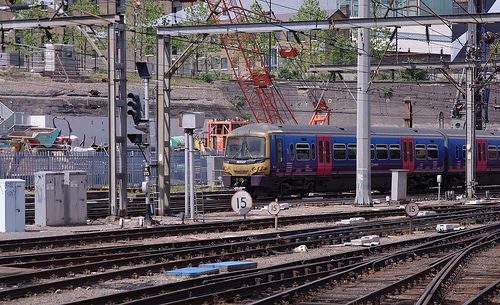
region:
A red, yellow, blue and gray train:
[217, 114, 498, 203]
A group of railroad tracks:
[9, 209, 498, 302]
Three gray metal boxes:
[6, 165, 93, 231]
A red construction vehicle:
[189, 5, 333, 160]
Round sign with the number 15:
[224, 184, 254, 221]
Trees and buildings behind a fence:
[3, 1, 496, 90]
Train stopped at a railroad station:
[6, 103, 498, 297]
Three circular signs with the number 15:
[214, 177, 427, 239]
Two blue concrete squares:
[163, 255, 256, 281]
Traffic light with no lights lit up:
[120, 78, 169, 226]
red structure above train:
[199, 0, 306, 123]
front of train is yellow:
[209, 119, 296, 186]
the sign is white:
[195, 178, 260, 223]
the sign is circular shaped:
[217, 188, 263, 220]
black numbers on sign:
[222, 184, 261, 221]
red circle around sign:
[214, 178, 260, 224]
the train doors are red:
[314, 126, 498, 185]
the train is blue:
[251, 110, 498, 192]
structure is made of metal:
[4, 16, 494, 201]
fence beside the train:
[6, 134, 249, 185]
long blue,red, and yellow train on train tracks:
[220, 118, 498, 188]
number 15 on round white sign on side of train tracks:
[217, 183, 258, 224]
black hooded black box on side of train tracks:
[132, 54, 154, 83]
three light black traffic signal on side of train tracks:
[121, 86, 151, 130]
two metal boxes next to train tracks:
[30, 167, 92, 225]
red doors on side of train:
[310, 134, 337, 175]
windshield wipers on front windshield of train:
[232, 138, 256, 162]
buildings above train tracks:
[2, 3, 312, 80]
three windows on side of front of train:
[284, 139, 319, 163]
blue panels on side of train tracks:
[161, 258, 263, 278]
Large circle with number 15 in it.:
[229, 190, 252, 216]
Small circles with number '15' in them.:
[262, 202, 421, 216]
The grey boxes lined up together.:
[0, 166, 90, 226]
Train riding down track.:
[220, 116, 491, 186]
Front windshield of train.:
[220, 130, 265, 165]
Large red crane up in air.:
[210, 0, 296, 122]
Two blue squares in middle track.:
[162, 256, 267, 280]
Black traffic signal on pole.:
[128, 89, 143, 128]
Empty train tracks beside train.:
[5, 205, 499, 303]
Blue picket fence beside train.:
[2, 149, 226, 186]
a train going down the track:
[224, 122, 499, 194]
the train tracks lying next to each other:
[5, 205, 491, 303]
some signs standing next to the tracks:
[228, 189, 282, 220]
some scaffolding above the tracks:
[11, 10, 498, 201]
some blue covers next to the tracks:
[168, 255, 259, 276]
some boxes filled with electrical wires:
[1, 168, 89, 229]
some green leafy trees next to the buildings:
[236, 15, 379, 70]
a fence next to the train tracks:
[4, 153, 226, 183]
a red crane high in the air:
[208, 0, 305, 120]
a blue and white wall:
[370, 17, 464, 62]